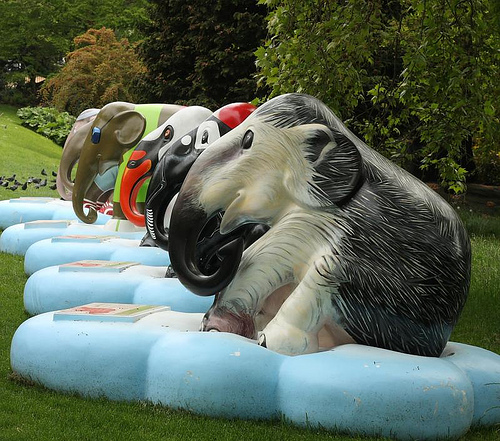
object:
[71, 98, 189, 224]
elephant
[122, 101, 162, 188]
torso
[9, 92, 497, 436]
statue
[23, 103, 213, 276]
statue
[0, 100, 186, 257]
statue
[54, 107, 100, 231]
statue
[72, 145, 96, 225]
green trunk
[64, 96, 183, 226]
statue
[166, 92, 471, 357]
elephant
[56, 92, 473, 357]
elephants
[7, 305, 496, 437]
base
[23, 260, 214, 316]
base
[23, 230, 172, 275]
base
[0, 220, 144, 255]
base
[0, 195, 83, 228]
base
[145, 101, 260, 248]
statue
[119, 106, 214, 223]
statue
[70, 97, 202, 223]
statue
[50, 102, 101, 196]
statue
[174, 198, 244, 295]
trunk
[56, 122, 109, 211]
statute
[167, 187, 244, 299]
trunk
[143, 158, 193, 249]
trunk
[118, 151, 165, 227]
trunk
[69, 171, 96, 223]
trunk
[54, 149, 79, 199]
trunk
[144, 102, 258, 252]
elephant statue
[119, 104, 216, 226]
elephant statue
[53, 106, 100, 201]
elephant statue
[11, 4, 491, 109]
trees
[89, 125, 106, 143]
strip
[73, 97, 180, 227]
statue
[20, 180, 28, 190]
bird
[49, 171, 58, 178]
bird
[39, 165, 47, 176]
bird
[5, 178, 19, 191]
bird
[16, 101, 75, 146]
bushes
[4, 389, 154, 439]
ground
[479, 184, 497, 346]
ground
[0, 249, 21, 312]
ground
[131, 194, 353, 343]
trunks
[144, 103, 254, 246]
statute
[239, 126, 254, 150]
eye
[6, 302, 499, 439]
stone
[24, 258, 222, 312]
stone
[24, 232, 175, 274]
stone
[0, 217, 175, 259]
stone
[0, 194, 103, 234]
stone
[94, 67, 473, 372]
trunk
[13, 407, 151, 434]
surfboard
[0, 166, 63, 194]
birds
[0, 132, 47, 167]
grass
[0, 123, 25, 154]
grass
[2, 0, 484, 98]
background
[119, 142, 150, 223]
trunk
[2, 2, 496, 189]
trees